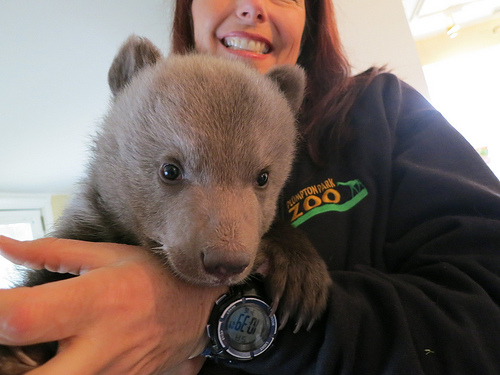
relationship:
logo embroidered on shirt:
[282, 172, 368, 226] [297, 102, 491, 367]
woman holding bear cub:
[188, 1, 499, 373] [64, 34, 335, 316]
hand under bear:
[0, 230, 230, 373] [1, 35, 331, 373]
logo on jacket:
[282, 172, 368, 226] [199, 72, 500, 375]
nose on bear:
[198, 245, 252, 279] [59, 31, 343, 329]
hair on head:
[293, 30, 384, 127] [171, 0, 354, 110]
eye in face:
[158, 160, 185, 185] [120, 141, 296, 286]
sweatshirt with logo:
[199, 67, 499, 374] [285, 174, 368, 231]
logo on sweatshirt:
[282, 172, 368, 226] [22, 62, 498, 368]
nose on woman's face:
[236, 1, 264, 23] [184, 3, 319, 69]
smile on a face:
[217, 27, 278, 59] [2, 0, 499, 374]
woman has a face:
[1, 0, 498, 374] [2, 0, 499, 374]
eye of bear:
[163, 166, 180, 181] [1, 35, 331, 373]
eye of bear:
[255, 172, 266, 186] [1, 35, 331, 373]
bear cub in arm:
[56, 25, 336, 340] [323, 249, 498, 354]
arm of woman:
[323, 249, 498, 354] [188, 1, 499, 373]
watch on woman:
[196, 273, 282, 375] [159, 9, 399, 369]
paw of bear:
[259, 225, 335, 328] [20, 32, 309, 373]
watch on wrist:
[198, 277, 287, 362] [178, 233, 302, 373]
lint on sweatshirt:
[422, 346, 434, 356] [199, 67, 499, 374]